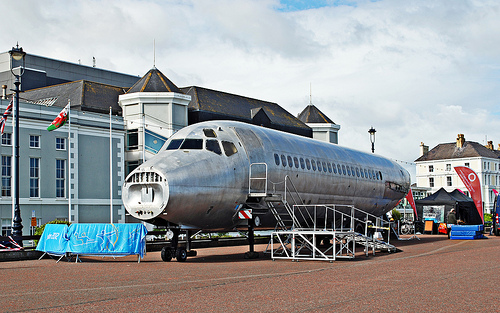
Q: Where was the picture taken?
A: It was taken at the display.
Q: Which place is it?
A: It is a display.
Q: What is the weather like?
A: It is cloudy.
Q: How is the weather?
A: It is cloudy.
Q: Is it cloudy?
A: Yes, it is cloudy.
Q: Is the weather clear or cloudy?
A: It is cloudy.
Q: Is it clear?
A: No, it is cloudy.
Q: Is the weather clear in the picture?
A: No, it is cloudy.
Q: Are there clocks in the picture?
A: No, there are no clocks.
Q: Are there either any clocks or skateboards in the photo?
A: No, there are no clocks or skateboards.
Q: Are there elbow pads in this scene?
A: No, there are no elbow pads.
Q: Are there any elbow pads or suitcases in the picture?
A: No, there are no elbow pads or suitcases.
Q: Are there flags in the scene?
A: Yes, there is a flag.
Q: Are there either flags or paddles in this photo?
A: Yes, there is a flag.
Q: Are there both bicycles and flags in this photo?
A: No, there is a flag but no bicycles.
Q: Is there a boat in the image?
A: No, there are no boats.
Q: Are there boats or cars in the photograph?
A: No, there are no boats or cars.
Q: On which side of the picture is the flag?
A: The flag is on the left of the image.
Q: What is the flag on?
A: The flag is on the pole.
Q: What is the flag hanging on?
A: The flag is hanging on the pole.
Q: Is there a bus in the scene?
A: No, there are no buses.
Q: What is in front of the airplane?
A: The sign is in front of the airplane.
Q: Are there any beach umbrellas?
A: No, there are no beach umbrellas.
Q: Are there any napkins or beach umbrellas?
A: No, there are no beach umbrellas or napkins.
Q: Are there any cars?
A: No, there are no cars.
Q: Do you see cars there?
A: No, there are no cars.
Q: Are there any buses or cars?
A: No, there are no cars or buses.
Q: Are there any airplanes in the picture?
A: Yes, there is an airplane.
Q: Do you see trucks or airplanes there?
A: Yes, there is an airplane.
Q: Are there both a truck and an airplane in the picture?
A: No, there is an airplane but no trucks.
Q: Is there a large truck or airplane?
A: Yes, there is a large airplane.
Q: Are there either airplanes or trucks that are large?
A: Yes, the airplane is large.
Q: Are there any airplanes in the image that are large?
A: Yes, there is a large airplane.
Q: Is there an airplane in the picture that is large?
A: Yes, there is an airplane that is large.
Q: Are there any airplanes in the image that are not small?
A: Yes, there is a large airplane.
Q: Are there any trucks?
A: No, there are no trucks.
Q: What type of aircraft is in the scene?
A: The aircraft is an airplane.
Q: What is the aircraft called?
A: The aircraft is an airplane.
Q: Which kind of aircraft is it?
A: The aircraft is an airplane.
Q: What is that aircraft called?
A: This is an airplane.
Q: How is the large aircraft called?
A: The aircraft is an airplane.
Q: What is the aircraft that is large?
A: The aircraft is an airplane.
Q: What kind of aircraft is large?
A: The aircraft is an airplane.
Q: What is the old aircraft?
A: The aircraft is an airplane.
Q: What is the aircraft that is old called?
A: The aircraft is an airplane.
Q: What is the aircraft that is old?
A: The aircraft is an airplane.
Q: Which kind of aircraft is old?
A: The aircraft is an airplane.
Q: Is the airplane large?
A: Yes, the airplane is large.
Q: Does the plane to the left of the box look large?
A: Yes, the plane is large.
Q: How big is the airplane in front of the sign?
A: The plane is large.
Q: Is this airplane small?
A: No, the airplane is large.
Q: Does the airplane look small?
A: No, the airplane is large.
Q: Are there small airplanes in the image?
A: No, there is an airplane but it is large.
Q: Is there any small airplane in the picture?
A: No, there is an airplane but it is large.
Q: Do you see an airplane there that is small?
A: No, there is an airplane but it is large.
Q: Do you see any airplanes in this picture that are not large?
A: No, there is an airplane but it is large.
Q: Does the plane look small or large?
A: The plane is large.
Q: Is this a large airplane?
A: Yes, this is a large airplane.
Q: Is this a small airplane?
A: No, this is a large airplane.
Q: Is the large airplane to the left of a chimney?
A: Yes, the airplane is to the left of a chimney.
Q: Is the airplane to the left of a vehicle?
A: No, the airplane is to the left of a chimney.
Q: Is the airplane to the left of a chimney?
A: Yes, the airplane is to the left of a chimney.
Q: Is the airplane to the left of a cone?
A: No, the airplane is to the left of a chimney.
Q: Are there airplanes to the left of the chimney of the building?
A: Yes, there is an airplane to the left of the chimney.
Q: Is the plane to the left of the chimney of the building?
A: Yes, the plane is to the left of the chimney.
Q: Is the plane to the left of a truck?
A: No, the plane is to the left of the chimney.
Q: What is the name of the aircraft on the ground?
A: The aircraft is an airplane.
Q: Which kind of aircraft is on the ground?
A: The aircraft is an airplane.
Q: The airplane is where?
A: The airplane is on the ground.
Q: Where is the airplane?
A: The airplane is on the ground.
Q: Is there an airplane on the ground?
A: Yes, there is an airplane on the ground.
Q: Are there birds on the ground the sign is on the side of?
A: No, there is an airplane on the ground.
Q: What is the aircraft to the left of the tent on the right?
A: The aircraft is an airplane.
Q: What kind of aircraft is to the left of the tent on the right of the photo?
A: The aircraft is an airplane.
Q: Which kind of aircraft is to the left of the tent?
A: The aircraft is an airplane.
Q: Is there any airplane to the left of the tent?
A: Yes, there is an airplane to the left of the tent.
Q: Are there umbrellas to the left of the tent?
A: No, there is an airplane to the left of the tent.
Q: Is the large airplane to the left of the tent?
A: Yes, the plane is to the left of the tent.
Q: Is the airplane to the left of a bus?
A: No, the airplane is to the left of the tent.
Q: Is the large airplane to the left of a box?
A: Yes, the plane is to the left of a box.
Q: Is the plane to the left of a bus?
A: No, the plane is to the left of a box.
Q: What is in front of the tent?
A: The airplane is in front of the tent.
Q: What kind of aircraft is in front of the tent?
A: The aircraft is an airplane.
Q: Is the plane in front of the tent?
A: Yes, the plane is in front of the tent.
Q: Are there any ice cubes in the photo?
A: No, there are no ice cubes.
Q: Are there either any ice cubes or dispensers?
A: No, there are no ice cubes or dispensers.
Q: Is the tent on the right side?
A: Yes, the tent is on the right of the image.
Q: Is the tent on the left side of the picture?
A: No, the tent is on the right of the image.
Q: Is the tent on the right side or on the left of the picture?
A: The tent is on the right of the image.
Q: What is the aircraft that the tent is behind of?
A: The aircraft is an airplane.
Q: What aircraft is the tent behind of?
A: The tent is behind the airplane.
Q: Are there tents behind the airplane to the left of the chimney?
A: Yes, there is a tent behind the plane.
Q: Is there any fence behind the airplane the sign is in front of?
A: No, there is a tent behind the airplane.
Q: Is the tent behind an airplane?
A: Yes, the tent is behind an airplane.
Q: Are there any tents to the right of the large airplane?
A: Yes, there is a tent to the right of the airplane.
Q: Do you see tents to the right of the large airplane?
A: Yes, there is a tent to the right of the airplane.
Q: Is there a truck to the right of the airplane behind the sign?
A: No, there is a tent to the right of the airplane.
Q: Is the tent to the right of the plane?
A: Yes, the tent is to the right of the plane.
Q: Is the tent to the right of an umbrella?
A: No, the tent is to the right of the plane.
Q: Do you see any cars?
A: No, there are no cars.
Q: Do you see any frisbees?
A: No, there are no frisbees.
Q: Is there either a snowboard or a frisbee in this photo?
A: No, there are no frisbees or snowboards.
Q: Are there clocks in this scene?
A: No, there are no clocks.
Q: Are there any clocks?
A: No, there are no clocks.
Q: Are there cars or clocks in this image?
A: No, there are no clocks or cars.